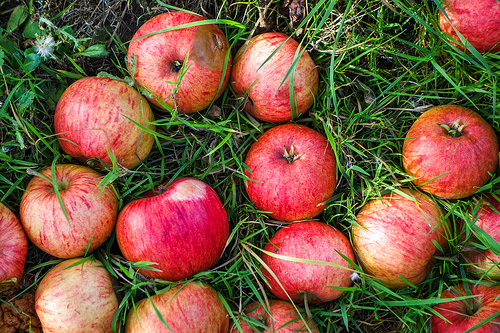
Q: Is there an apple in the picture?
A: Yes, there is an apple.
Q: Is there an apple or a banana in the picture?
A: Yes, there is an apple.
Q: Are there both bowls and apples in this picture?
A: No, there is an apple but no bowls.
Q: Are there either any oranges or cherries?
A: No, there are no oranges or cherries.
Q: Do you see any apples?
A: Yes, there is an apple.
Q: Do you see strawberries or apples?
A: Yes, there is an apple.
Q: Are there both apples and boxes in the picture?
A: No, there is an apple but no boxes.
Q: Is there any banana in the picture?
A: No, there are no bananas.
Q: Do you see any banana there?
A: No, there are no bananas.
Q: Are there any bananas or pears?
A: No, there are no bananas or pears.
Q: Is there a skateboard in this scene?
A: No, there are no skateboards.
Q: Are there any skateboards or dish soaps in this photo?
A: No, there are no skateboards or dish soaps.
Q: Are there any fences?
A: No, there are no fences.